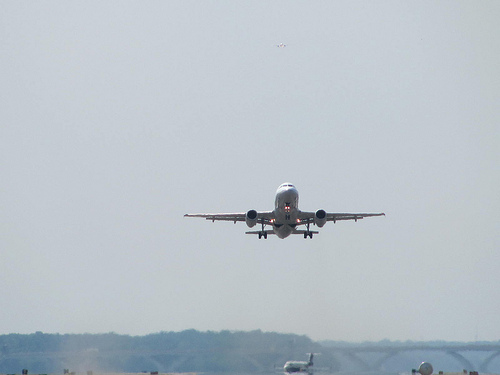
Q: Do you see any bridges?
A: Yes, there is a bridge.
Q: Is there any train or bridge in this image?
A: Yes, there is a bridge.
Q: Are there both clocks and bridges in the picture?
A: No, there is a bridge but no clocks.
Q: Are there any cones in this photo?
A: No, there are no cones.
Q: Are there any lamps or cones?
A: No, there are no cones or lamps.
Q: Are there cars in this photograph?
A: No, there are no cars.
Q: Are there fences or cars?
A: No, there are no cars or fences.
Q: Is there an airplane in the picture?
A: Yes, there is an airplane.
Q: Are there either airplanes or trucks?
A: Yes, there is an airplane.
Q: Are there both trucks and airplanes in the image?
A: No, there is an airplane but no trucks.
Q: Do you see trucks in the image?
A: No, there are no trucks.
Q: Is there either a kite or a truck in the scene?
A: No, there are no trucks or kites.